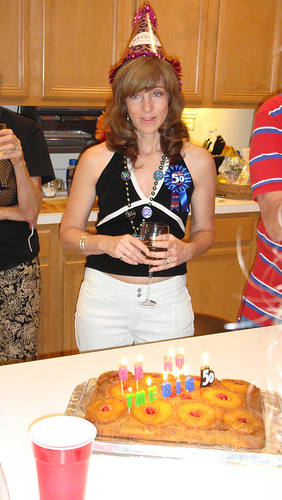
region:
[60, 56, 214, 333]
Woman standing with a drink in her hands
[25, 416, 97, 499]
Red cup with a white inside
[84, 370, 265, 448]
Pineapple upside down cake sitting on a platter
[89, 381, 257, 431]
Pineapples on top of cake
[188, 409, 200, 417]
A cherry in the middle of the sliced pineapple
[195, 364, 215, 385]
Brown and white sign on the cake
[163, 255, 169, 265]
gold ring on woman's left hand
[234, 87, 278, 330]
Red, blue and white top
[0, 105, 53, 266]
Person wearing a black top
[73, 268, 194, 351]
white pants worn by woman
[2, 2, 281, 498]
A birth day party to celebrate a half century of life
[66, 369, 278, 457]
A pineapple birthday cake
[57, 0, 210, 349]
The birthday girl herself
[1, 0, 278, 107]
Brown kitchen cabinets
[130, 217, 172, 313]
A soon to be empty then refilled and emptied again wineglass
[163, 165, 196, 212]
A birthday girl ribbon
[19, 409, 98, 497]
A red party cup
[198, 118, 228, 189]
A well used knife holder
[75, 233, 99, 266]
Two golden bracelets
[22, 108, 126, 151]
An old toaster oven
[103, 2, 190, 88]
Birthday hat on the woman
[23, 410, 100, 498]
Red cup on the table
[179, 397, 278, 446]
pineapple slices on a cake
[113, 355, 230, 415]
candles on a cake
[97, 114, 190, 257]
beads on a womans neck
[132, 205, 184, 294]
woman holding a wine glass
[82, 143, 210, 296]
woman wearing black shirt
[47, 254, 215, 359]
woman wearing white pants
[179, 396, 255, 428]
Cherries inside pineaplle slices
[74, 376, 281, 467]
Cake sitting on a cake pan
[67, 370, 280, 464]
a Pineapple Upside-Down cake in a silver colored tray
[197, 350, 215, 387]
a burning candle with the number 50 on it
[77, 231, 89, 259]
woman wearing a silver colored bracelet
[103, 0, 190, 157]
woman wearing a pointed party hat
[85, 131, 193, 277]
woman wearing a black top with white trim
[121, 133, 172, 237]
woman wearing a party-themed necklace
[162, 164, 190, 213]
blue ribbon with the number 50 on it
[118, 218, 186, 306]
woman holding a wine glass in front of her torso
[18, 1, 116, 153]
toaster oven beneath a cabinet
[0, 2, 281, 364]
people standing to the left and right of woman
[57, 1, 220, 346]
Lady turning 50 in the birthday hat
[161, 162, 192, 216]
Blue turning 50 ribbon on the woman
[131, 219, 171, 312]
Wine glass held by the woman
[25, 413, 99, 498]
Red plastic cup on the counter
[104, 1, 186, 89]
Birthday party hat on the woman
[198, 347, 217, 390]
Black fifty candle on the cake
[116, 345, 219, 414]
Group of lit candles on the birthday cake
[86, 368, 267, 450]
Pineapple upside down birthday cake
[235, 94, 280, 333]
Red shirt with blue and white stripes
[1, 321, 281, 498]
White coutertop in front of the people